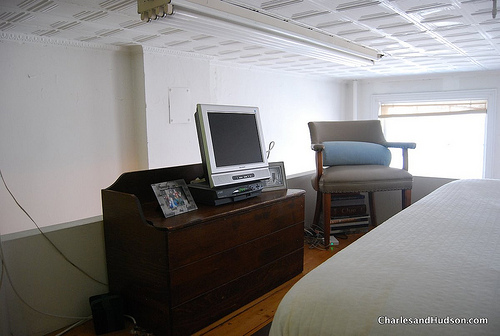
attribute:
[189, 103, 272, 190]
television — silver, on, off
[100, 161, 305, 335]
dresser — brown, wooden, dark brown, wood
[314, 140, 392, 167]
pillow — blue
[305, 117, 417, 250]
chair — gray, light brown, tan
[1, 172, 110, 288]
wire — black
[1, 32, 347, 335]
wall — white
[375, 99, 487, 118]
blinds — white, rolled up, open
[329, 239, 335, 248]
light — green, little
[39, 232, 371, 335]
floor — hard wood, light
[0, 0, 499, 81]
ceiling — white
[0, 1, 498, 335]
room — very plain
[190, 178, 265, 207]
cable box — black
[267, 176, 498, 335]
bed — large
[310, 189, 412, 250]
legs — wood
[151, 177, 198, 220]
picture frame — silver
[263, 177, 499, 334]
comforter — white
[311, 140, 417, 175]
armrests — wood